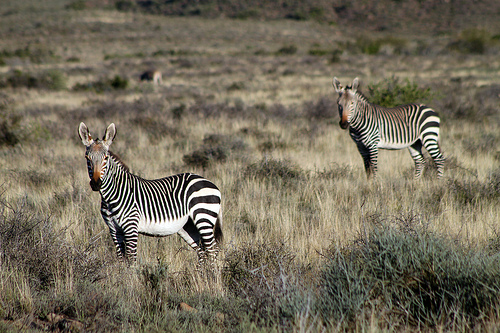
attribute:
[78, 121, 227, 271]
zebra — standing, black, white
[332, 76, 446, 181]
zebra — standing, black, white, brown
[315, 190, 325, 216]
grass — brown, dry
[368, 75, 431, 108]
shrub — green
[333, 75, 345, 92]
ear — pointy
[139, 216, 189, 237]
belly — white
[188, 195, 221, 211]
stripe — black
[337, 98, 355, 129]
face — brown, black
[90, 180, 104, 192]
nose — black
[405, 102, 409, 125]
stripe — black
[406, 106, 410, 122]
stripe — brown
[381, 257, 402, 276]
grass — green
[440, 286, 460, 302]
grass — green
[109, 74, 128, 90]
bush — small, green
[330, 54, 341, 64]
bush — small, green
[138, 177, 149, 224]
stripe — long, black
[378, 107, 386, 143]
stripe — long, black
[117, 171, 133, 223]
stripe — long, black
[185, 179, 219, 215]
stripe — thick, black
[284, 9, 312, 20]
shrub — green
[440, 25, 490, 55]
shrub — green